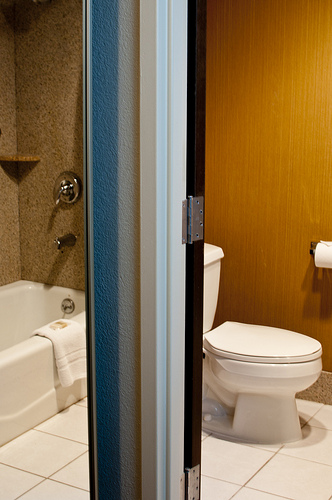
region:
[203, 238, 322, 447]
White toilet in the room.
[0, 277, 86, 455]
White tub on the bathroom.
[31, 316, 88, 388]
White towel on the bathtub.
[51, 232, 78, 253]
Silver faucet on the wall.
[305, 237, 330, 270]
toilet paper on the wall.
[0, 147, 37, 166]
Shelf in the tub wall.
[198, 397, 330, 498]
White tile on the floor.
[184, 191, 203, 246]
Silver hinge on the door.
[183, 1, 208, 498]
Brown door in the room.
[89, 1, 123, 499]
Blue line on the wall.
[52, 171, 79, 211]
chrome all-in-one shower faucet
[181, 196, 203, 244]
silver door hinge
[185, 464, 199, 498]
silver door hinge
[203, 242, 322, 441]
white porcelain toilet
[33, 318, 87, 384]
white bathmat hanging on side of bathtub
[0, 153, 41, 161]
shower corner shelf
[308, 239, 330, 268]
toilet paper on toilet paper holder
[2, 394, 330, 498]
white tile bathroom floor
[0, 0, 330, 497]
bathroom with white tub and toilet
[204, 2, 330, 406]
yellow orange bathroom wall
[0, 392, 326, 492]
tile in white color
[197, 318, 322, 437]
toilet is white in color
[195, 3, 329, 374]
toilet tissue hanging by wood panel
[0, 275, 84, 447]
white towel hanging on bathtub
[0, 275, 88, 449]
bathtub is white in color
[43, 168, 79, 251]
pipe is silver in color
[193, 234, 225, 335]
tank is white in color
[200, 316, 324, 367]
toilet cover is white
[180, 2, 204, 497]
toilet door is black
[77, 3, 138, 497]
door has blue on it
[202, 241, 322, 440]
toilet used for disposing of bodily wastes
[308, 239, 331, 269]
roll of toilet paper used for cleaning butt after toilet use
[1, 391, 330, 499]
tile floors are easier to manage, especially in case of toilet/tub leaks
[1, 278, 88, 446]
bathtub for bathing in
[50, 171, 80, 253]
faucet and knob to control the amount of water and temperature of water released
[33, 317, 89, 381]
towel to use for drying off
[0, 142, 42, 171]
mini shelf in shower good for holding shower items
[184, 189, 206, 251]
door henge indicates there's a door here.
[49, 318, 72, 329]
mini soap bar indicate this may be a hotel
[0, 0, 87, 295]
granite or marble shower wall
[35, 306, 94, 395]
towel on the side of the tub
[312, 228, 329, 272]
toilet paper roll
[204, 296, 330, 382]
toilet seat is down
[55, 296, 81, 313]
tub plug under faucet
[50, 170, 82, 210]
hot and cold knob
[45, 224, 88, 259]
water faucet on the wall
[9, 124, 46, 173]
shelf for items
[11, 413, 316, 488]
white tiles on the floors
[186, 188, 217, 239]
hinge for door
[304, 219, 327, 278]
toilet paper holder on the wall